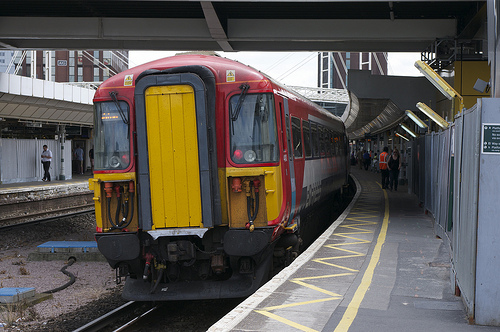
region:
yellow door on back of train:
[155, 105, 185, 175]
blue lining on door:
[201, 122, 206, 159]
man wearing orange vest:
[378, 153, 387, 165]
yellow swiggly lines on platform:
[342, 229, 362, 261]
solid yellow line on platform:
[368, 258, 378, 275]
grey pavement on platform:
[399, 262, 416, 290]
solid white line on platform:
[289, 261, 300, 270]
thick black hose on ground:
[56, 266, 80, 289]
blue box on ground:
[48, 238, 70, 251]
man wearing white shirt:
[46, 153, 51, 157]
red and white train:
[94, 48, 378, 265]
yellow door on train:
[114, 83, 231, 247]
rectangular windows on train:
[220, 87, 294, 177]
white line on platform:
[251, 197, 382, 329]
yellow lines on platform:
[281, 183, 392, 330]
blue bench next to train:
[32, 220, 103, 274]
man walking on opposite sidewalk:
[37, 137, 57, 192]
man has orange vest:
[374, 140, 394, 181]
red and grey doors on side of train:
[252, 87, 293, 202]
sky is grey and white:
[238, 51, 313, 91]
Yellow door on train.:
[150, 89, 199, 239]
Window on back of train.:
[235, 98, 273, 174]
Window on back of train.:
[96, 97, 155, 184]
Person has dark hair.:
[36, 139, 54, 157]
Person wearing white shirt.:
[30, 146, 70, 162]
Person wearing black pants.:
[36, 158, 58, 174]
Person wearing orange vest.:
[373, 150, 399, 173]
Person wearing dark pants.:
[374, 168, 401, 199]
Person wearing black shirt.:
[386, 154, 405, 174]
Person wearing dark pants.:
[387, 169, 404, 184]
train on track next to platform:
[65, 34, 452, 328]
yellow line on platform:
[340, 173, 402, 329]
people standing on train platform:
[358, 135, 415, 207]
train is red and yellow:
[69, 55, 317, 268]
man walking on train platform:
[29, 127, 59, 178]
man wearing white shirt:
[34, 144, 59, 164]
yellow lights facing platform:
[384, 62, 477, 156]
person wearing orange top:
[374, 147, 392, 173]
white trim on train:
[285, 153, 351, 203]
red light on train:
[226, 130, 274, 183]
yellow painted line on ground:
[259, 293, 337, 305]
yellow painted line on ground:
[258, 310, 319, 329]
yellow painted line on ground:
[290, 278, 341, 294]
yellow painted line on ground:
[298, 270, 355, 283]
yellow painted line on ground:
[313, 260, 355, 273]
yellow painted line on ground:
[314, 251, 366, 263]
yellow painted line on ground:
[326, 242, 365, 256]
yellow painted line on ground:
[332, 231, 369, 243]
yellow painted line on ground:
[343, 221, 373, 234]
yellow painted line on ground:
[351, 210, 380, 220]